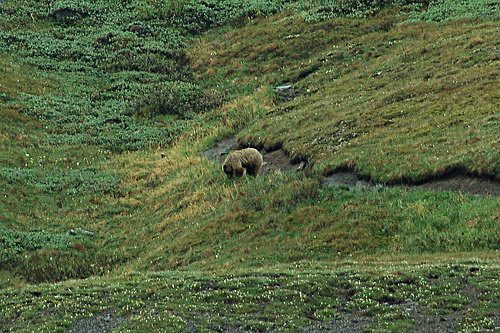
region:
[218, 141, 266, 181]
a brown bear on the grass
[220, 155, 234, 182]
the head of a bear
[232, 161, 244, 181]
the leg of a bear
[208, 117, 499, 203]
a brown dirt path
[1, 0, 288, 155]
green leafy bushes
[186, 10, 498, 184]
a grassy green field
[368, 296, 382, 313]
a white flower in the grass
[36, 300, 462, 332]
gravel on the ground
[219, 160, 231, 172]
the ear of a bear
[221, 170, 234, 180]
the snout of a bear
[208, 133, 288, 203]
the bear is brown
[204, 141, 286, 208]
the bear has its head down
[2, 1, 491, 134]
the grass is filled with shrubs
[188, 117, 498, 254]
a dirt path is in the grass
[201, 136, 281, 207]
the bear's legs are darker then upper body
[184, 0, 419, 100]
brown spots are in the grass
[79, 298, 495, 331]
the grass has rocks in it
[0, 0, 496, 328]
the grass is wet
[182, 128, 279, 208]
the bear is by itself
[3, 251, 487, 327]
small flowers are growing in the grass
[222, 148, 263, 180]
brown bear looking for food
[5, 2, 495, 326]
brown bear in the wild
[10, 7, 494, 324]
bear standing on the ground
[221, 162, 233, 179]
head of bear sniffing the grass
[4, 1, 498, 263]
green weeds and grass on the gound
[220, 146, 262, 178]
bear standing on the ground eating grass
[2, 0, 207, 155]
wild green grass on the ground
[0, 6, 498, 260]
brown and grey bear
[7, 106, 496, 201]
bear eating below a hill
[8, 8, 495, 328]
brown eating in an open field in the wilderness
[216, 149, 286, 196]
A BROWN BEAR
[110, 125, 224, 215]
YELLOW AND GREEN GRASS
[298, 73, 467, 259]
A GRASSY HILL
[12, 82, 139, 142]
A GREEN PATCH OF GRASS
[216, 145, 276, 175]
A BROWN BEAR ON A HILL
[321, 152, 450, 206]
TRAIL THROUGH THE GRASS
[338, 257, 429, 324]
WHITE FLOWERS IN THE GRASS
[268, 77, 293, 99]
A GRAY ROCK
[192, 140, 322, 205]
A BEAR IN A FIELD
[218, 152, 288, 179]
A BEAR HUNTING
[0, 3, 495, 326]
a large green field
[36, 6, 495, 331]
a bear in a green field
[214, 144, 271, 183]
a bear bending forwards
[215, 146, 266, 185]
a bear looking for food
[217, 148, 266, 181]
a small brown bear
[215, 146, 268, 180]
a light brown bear with dark brown feet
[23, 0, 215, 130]
a bed of clover in a field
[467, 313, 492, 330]
a clump of small white flowers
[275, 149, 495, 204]
a long patch of dirt in the field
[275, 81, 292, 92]
something white hidden in the grass